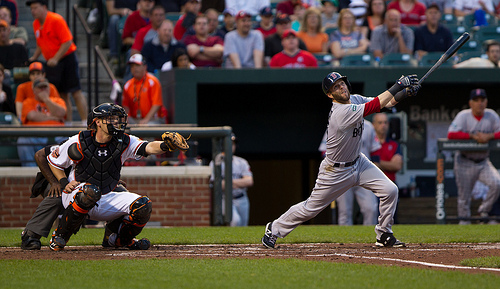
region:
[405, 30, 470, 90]
A professional baseball bat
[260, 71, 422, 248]
A baseball player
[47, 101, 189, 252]
A catcher getting ready to catch ball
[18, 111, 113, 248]
Umpire behind the catcher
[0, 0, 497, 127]
People in the audience watching the game.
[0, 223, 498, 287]
A baseball field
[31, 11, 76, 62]
A bright orange tee shirt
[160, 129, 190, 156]
A baseball glove on man's hand.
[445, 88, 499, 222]
A baseball player in the dugout.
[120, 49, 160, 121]
spectator in the stand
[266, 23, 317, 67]
spectator in the stand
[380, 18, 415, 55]
spectator in the stand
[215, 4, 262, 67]
spectator in the stand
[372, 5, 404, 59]
spectator in the stand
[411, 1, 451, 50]
spectator in the stand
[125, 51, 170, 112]
spectator in the stand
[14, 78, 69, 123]
spectator in the stand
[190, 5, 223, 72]
spectator in the stand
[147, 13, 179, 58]
spectator in the stand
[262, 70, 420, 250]
the batter in motion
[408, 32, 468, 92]
the bat in the batter's hand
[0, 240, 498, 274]
the dirt on the baseball field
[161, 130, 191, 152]
the glove on the catcher's hand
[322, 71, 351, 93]
the helmet on the batter's head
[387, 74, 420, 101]
the gloves on the batter's hands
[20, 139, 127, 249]
the umpire behind the catcher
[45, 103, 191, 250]
the catcher crouching down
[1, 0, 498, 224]
the people watching the baseball game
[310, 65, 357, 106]
a player wearing a blue helmet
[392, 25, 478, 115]
a player swinging a bat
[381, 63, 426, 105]
a player wearing batting gloves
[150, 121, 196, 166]
a player wearing a catchers mitt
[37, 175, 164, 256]
a catcher wearing knee pads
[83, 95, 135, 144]
a catcher wearing a mask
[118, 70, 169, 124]
a man wearing an orange shirt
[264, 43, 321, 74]
a man wearing a red shirt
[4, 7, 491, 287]
Photo taken during the day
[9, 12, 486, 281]
Photo taken at a baseball field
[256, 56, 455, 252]
Right handed batter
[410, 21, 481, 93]
Black baseball bat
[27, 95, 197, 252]
Catcher crouched down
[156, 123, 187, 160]
Glove on the catcher's left hand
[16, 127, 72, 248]
Umpire behind the catcher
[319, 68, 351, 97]
Helmet on the batter's head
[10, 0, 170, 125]
Spectators wearing orange shirts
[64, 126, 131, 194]
Black chest protector on the catcher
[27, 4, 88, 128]
man wearing orange shirt and black shorts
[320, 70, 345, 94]
black safety helmet with white and red emblem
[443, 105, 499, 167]
white short sleeved shirt over red long sleeved shirt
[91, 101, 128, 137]
black catcher's mitt with face plate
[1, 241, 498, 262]
brown dirt in middle of grass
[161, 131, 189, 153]
a brown baseball mitt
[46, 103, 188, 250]
the catcher is squatted on the ground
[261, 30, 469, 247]
a baseball player holding a baseball bat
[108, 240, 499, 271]
white lines on a baseball field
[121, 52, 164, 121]
a person wearing an orange shirt and baseball cap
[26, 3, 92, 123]
a man wearing a bright orange shirt and black shorts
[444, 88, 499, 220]
a man wearing a baseball outfit and baseball cap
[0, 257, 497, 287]
grassy area on the baseball field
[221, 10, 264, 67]
a man wearing a gray shirt